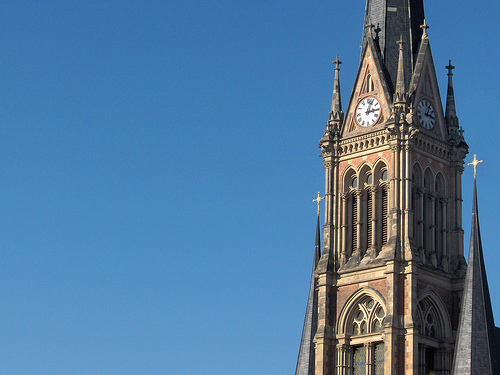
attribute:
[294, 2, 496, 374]
tower — large, clock tower, red, brown, tall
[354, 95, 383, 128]
clock — round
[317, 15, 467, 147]
spires — grey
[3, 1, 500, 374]
sky — clear, blue, cloudless, sunny, deep blue, blocked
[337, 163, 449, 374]
windows — rounded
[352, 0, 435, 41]
steeple — tall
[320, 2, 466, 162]
tops — decorative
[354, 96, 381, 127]
numbers — roman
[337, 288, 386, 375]
window — ornate, arched, first window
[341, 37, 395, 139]
panel — triangular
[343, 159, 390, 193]
arches — window arches, skinny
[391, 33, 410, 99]
spire — mini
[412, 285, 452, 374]
window — second window